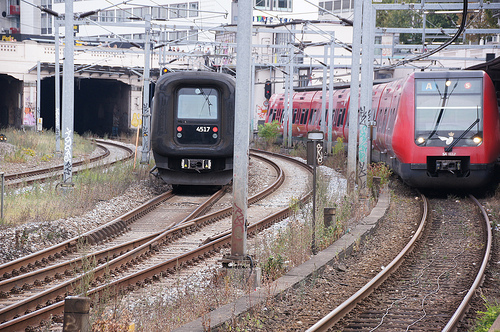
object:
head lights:
[175, 125, 182, 133]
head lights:
[414, 136, 429, 145]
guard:
[426, 154, 471, 177]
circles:
[211, 132, 220, 140]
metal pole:
[230, 0, 255, 254]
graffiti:
[233, 202, 243, 241]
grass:
[246, 283, 254, 322]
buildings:
[0, 0, 499, 134]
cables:
[303, 0, 353, 28]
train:
[147, 70, 234, 198]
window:
[414, 109, 478, 131]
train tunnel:
[39, 76, 132, 136]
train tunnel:
[0, 71, 23, 128]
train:
[263, 69, 498, 197]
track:
[301, 188, 495, 332]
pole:
[311, 168, 315, 255]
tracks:
[0, 137, 135, 187]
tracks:
[1, 145, 313, 330]